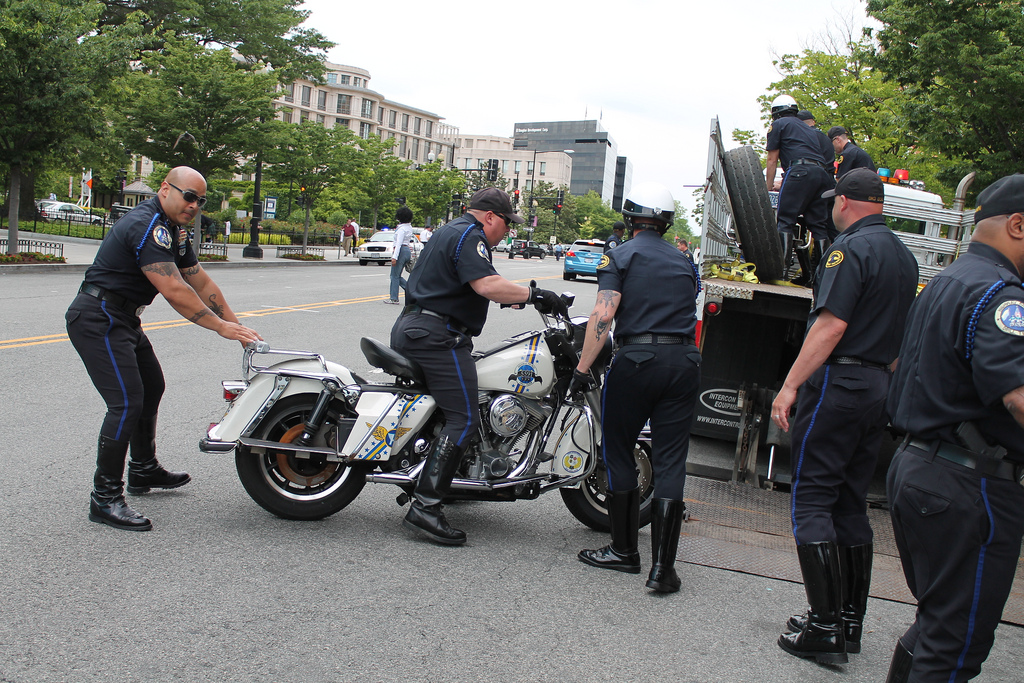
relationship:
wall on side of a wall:
[61, 52, 571, 228] [124, 64, 571, 227]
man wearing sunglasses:
[57, 156, 261, 533] [178, 188, 202, 202]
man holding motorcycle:
[57, 156, 261, 533] [195, 290, 666, 517]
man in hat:
[392, 180, 568, 550] [467, 184, 532, 224]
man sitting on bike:
[392, 180, 568, 550] [202, 282, 660, 532]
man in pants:
[755, 89, 829, 273] [772, 163, 829, 269]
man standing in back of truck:
[755, 89, 829, 273] [675, 109, 965, 485]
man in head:
[564, 171, 714, 593] [622, 186, 676, 237]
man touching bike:
[564, 171, 714, 593] [202, 282, 660, 532]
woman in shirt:
[383, 199, 420, 314] [390, 217, 419, 257]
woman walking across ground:
[383, 199, 420, 314] [0, 254, 1024, 683]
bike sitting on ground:
[202, 282, 660, 532] [16, 229, 797, 673]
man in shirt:
[884, 186, 978, 664] [899, 238, 993, 457]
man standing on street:
[884, 186, 978, 664] [11, 201, 958, 660]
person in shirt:
[335, 215, 370, 259] [336, 217, 360, 237]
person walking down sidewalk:
[335, 215, 370, 259] [14, 227, 537, 262]